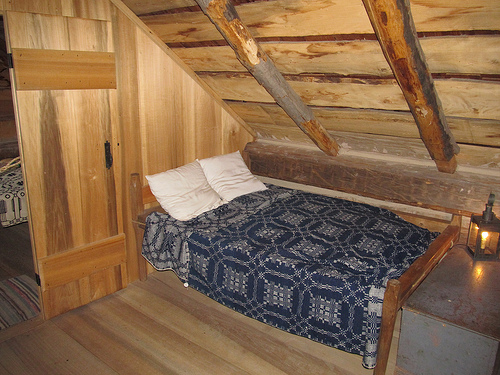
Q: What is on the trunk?
A: Lamp.